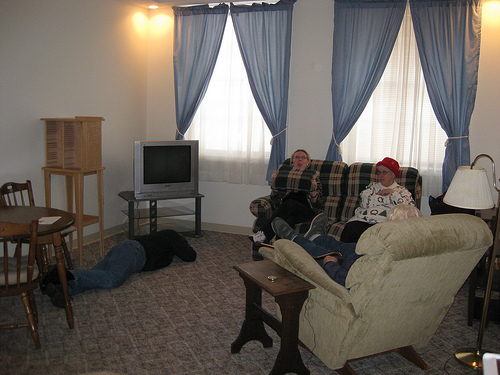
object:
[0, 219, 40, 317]
chair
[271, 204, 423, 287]
person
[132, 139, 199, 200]
television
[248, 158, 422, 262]
chair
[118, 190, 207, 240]
stand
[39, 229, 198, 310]
man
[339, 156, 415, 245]
woman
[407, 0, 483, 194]
blue curtain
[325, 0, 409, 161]
blue curtain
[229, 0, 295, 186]
blue curtain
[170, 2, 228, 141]
blue curtain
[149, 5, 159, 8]
lamp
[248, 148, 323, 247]
woman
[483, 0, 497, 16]
lights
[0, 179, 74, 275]
chair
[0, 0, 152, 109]
wall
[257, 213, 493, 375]
chair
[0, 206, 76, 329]
table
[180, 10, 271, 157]
window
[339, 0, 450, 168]
window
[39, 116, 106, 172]
box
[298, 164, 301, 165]
tongue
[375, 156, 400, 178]
hat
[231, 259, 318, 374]
side table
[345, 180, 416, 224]
sweater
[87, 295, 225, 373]
floor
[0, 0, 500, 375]
living room